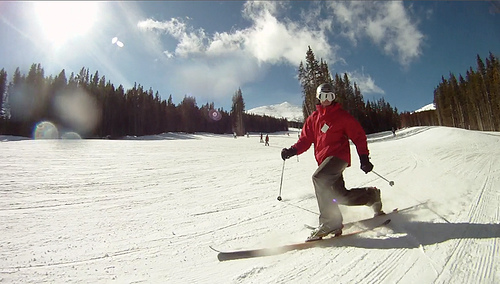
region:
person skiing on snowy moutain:
[253, 86, 376, 245]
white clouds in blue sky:
[18, 6, 77, 36]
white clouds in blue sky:
[8, 26, 87, 53]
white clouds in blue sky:
[98, 32, 192, 65]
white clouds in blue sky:
[150, 57, 218, 86]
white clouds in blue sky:
[127, 9, 230, 49]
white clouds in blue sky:
[223, 6, 338, 41]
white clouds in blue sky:
[171, 51, 279, 79]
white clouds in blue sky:
[324, 2, 402, 32]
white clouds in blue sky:
[359, 10, 423, 82]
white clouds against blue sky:
[0, 7, 79, 43]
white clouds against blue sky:
[15, 17, 113, 60]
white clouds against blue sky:
[135, 8, 196, 53]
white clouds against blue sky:
[188, 23, 258, 80]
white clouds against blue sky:
[245, 17, 358, 41]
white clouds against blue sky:
[352, 10, 425, 46]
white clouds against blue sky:
[390, 24, 436, 69]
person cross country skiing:
[205, 74, 399, 257]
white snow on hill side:
[28, 146, 120, 207]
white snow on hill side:
[168, 165, 253, 212]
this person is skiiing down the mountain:
[13, 19, 476, 273]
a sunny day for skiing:
[6, 8, 450, 138]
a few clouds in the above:
[130, 11, 445, 115]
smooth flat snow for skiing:
[21, 135, 498, 275]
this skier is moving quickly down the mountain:
[250, 78, 425, 262]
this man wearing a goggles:
[314, 81, 342, 113]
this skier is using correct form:
[215, 133, 407, 261]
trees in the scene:
[8, 61, 304, 143]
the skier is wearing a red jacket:
[285, 106, 385, 178]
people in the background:
[233, 123, 290, 154]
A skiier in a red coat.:
[202, 78, 416, 260]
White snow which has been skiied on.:
[47, 163, 219, 232]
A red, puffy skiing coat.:
[290, 102, 370, 164]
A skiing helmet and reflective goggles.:
[310, 80, 341, 106]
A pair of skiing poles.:
[270, 140, 400, 204]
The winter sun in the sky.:
[25, 0, 108, 45]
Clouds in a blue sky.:
[138, 0, 441, 101]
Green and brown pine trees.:
[430, 46, 497, 131]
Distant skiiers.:
[255, 128, 275, 148]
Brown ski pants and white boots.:
[307, 155, 383, 240]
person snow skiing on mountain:
[238, 82, 399, 251]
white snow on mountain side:
[25, 154, 111, 194]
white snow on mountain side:
[139, 158, 185, 179]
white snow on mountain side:
[203, 153, 249, 217]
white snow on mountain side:
[4, 177, 101, 267]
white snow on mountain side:
[138, 200, 182, 257]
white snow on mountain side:
[410, 145, 477, 187]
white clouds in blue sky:
[158, 33, 252, 77]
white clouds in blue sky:
[294, 24, 388, 44]